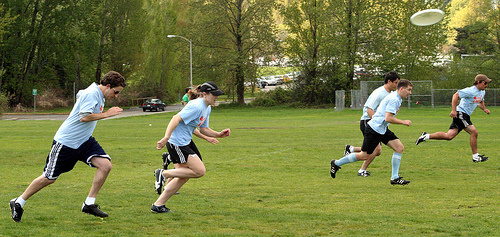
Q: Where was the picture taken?
A: In a field.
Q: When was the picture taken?
A: Daytime.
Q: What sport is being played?
A: Frisbee.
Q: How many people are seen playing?
A: Six.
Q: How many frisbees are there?
A: One.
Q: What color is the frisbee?
A: White.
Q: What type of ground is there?
A: Grass.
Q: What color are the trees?
A: Green.